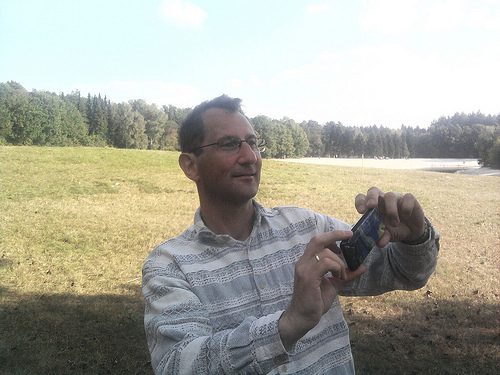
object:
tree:
[0, 88, 49, 144]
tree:
[139, 103, 169, 150]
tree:
[284, 117, 308, 156]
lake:
[406, 163, 500, 178]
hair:
[177, 93, 254, 158]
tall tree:
[84, 88, 93, 148]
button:
[257, 279, 266, 290]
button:
[279, 363, 291, 375]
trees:
[472, 122, 500, 171]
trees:
[400, 122, 410, 159]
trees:
[434, 115, 460, 157]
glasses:
[189, 137, 268, 155]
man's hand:
[352, 185, 433, 251]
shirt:
[137, 197, 442, 375]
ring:
[313, 252, 321, 263]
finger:
[302, 247, 350, 282]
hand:
[277, 229, 369, 352]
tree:
[247, 115, 280, 159]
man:
[136, 90, 442, 374]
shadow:
[0, 280, 500, 375]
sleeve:
[137, 247, 298, 375]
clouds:
[245, 0, 500, 131]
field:
[0, 146, 500, 375]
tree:
[53, 103, 93, 145]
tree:
[113, 106, 151, 149]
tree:
[271, 119, 299, 159]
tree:
[298, 120, 325, 157]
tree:
[430, 117, 459, 159]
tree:
[368, 124, 386, 159]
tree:
[332, 115, 352, 160]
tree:
[85, 92, 111, 146]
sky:
[0, 0, 500, 131]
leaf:
[301, 135, 306, 140]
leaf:
[146, 115, 154, 125]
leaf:
[91, 105, 100, 115]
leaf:
[118, 108, 137, 114]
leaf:
[16, 96, 22, 108]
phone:
[340, 205, 388, 274]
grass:
[15, 314, 113, 360]